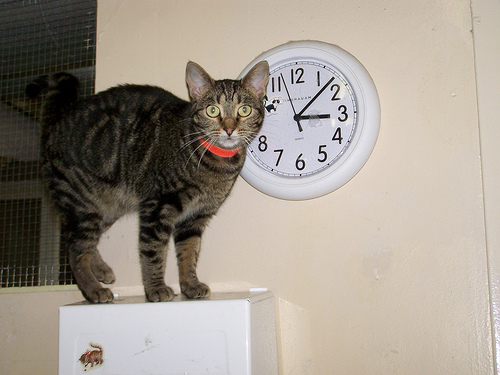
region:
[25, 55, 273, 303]
a gray and white cat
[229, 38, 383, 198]
a white closk on the wall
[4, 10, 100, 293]
a screen on th ewall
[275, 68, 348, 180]
numbers on a clock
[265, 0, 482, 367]
a white wall with a clock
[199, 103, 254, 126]
a yellow eyes on a cat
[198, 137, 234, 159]
a red collar on a cat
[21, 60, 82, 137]
a black and gray tail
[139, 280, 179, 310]
a gray and black foot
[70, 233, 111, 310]
a gray and black rear leg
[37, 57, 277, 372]
A cat ontop of a white metal box.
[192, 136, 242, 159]
The cat is wearing a red collar.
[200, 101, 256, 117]
The cat has green eyes.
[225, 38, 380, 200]
A round white clock with black numbers.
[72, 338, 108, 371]
A mouse image on the metal box.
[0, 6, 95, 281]
A metal grate over an opening.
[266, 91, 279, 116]
A black and white dog image on the clock.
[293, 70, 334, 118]
Black clock hands.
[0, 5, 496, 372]
A tan painted wall.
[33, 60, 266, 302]
Brown and white cat with black stripes.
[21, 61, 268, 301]
grey and black cat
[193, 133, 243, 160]
red collar on cat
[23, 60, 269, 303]
cat standing on cabinet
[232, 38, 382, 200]
white clock on wall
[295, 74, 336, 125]
black hands on clock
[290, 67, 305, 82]
number twelve on clock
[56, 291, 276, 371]
white cabinet on wall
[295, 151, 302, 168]
number six on clock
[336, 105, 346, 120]
number three on clock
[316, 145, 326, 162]
number five on clock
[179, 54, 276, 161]
the head of a cat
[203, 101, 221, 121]
the eye of a cat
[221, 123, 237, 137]
the nose of a cat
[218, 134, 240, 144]
the mouth of a cat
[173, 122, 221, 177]
the whiskers of a cat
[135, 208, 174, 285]
the leg of a cat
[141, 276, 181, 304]
the paw of a cat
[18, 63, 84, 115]
the tail of a cat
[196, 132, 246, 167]
a red collar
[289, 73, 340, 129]
the hands of a clock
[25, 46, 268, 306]
a gray and black cat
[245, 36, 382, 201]
a white clock on the wall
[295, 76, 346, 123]
hands on a clock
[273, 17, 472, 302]
a white wall with a clock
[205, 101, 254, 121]
yellow eyes of a cat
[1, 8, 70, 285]
metal screen on the wall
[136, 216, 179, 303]
a cats front leg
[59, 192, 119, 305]
a cats rear legs